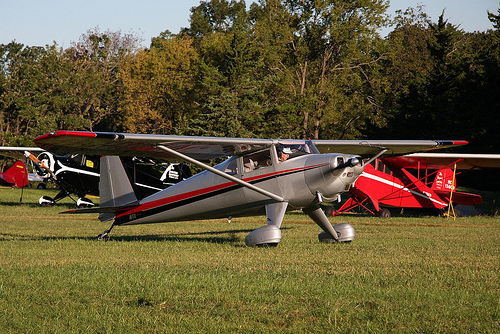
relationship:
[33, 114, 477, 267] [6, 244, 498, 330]
gray airplane on ground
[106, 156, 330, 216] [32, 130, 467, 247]
line on aircraft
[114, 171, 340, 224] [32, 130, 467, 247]
line on aircraft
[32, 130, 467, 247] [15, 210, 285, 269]
aircraft has a shadow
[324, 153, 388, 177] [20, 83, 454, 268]
engine on airplane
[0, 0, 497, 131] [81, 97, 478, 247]
trees behind airplanes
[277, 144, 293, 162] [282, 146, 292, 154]
person wearing cap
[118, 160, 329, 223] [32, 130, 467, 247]
line on aircraft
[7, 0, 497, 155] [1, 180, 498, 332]
trees on field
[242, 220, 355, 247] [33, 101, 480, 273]
gear on airplane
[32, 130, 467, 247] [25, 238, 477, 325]
aircraft on grass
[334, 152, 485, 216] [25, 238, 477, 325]
airplane on grass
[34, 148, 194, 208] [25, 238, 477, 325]
black airplane on grass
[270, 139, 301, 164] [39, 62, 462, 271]
person in plane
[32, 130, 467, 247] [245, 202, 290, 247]
aircraft has landing gear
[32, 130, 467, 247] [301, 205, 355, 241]
aircraft has landing gear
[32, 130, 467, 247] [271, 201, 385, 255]
aircraft has gear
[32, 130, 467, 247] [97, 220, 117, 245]
aircraft has gear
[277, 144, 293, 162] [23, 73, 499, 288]
person in airplane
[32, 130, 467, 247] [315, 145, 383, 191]
aircraft has propeller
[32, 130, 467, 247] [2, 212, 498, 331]
aircraft on grass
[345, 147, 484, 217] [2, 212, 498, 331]
plane on grass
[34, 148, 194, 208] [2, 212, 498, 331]
black airplane on grass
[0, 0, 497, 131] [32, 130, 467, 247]
trees near aircraft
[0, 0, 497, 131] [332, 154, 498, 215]
trees near plane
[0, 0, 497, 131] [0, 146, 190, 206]
trees near plane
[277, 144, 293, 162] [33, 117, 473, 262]
person in plane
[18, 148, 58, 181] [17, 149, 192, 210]
propeller on plane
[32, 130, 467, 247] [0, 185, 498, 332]
aircraft on grass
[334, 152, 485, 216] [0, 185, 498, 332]
airplane on grass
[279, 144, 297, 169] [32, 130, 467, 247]
pilot in aircraft